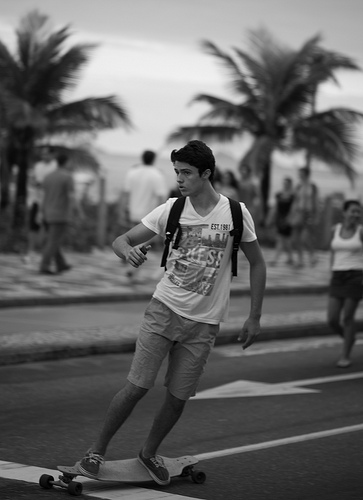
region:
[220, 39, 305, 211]
huge palm tree on sidewalk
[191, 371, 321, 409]
white arrow on the street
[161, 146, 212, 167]
short black hair cut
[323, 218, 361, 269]
woman wearing no sleeve white shirt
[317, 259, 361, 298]
woman wearing short black skirt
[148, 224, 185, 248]
silver buckle on back pack strap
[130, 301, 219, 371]
creases on brown shorts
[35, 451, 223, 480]
skate board on the street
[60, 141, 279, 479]
boy riding skate board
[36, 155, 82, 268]
man walking on side walk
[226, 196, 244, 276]
a black strap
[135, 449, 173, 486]
a man's tennis shoe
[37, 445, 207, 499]
a long skateboard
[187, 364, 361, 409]
part of a white arrow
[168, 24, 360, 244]
a large tree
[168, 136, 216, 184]
a man's short cut black hair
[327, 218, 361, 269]
a woman's white tank top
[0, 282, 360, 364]
part of a sidewalk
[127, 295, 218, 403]
a man's shorts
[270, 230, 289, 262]
the leg of a woman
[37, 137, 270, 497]
a male riding his skateboard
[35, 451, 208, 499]
a skateboard the kid is using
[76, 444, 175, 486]
shoes the kid is using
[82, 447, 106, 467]
shoelace of the shoe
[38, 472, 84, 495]
wheels of the skateboard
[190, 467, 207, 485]
wheel of the skateboard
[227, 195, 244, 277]
strap of the backpack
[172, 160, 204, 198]
facial expression of the kid on the skateboard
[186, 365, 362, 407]
an arrow on the road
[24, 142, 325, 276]
people walking in the sidewalk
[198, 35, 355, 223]
tall palm tree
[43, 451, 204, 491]
skateboard is bending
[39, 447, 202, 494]
two feet on the skateboard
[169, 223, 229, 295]
design on the white shirt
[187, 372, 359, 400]
arrow painted on the asphalt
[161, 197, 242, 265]
dark back pack straps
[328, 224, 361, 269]
plain white tank top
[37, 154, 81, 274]
man walking on the sidewalk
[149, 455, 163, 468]
white shoe laces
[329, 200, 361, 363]
woman is walking on the street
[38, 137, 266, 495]
boy riding a skateboard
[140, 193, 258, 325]
white short sleeve shirt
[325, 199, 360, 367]
woman walking in street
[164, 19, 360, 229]
tall palm tree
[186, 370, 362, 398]
white arrow painted on road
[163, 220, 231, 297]
guess logo on front of shirt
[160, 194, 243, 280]
black backpack straps over shoulders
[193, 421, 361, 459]
white stripe painted down center of road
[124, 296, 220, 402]
khaki shorts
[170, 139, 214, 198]
short brown hair on head